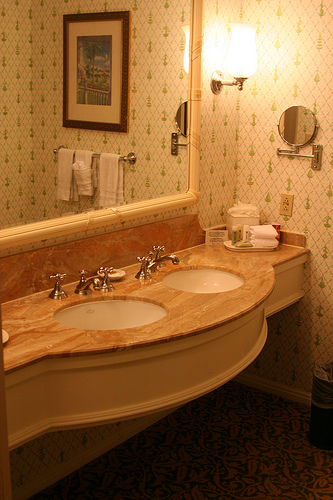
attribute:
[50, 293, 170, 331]
sink — white, marble, in the counter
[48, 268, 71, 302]
handle — silver, metal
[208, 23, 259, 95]
light — bright, a fixture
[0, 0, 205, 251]
mirror — over the counter, hung, large, white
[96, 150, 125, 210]
towel — folded, white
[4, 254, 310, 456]
base — white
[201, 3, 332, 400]
wall — papered, white, patterned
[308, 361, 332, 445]
trash — clear, black, bagged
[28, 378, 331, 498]
floor — patterned, carpeted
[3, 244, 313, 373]
counter — marble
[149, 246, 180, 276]
faucet — silver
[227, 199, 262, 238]
tissue — white